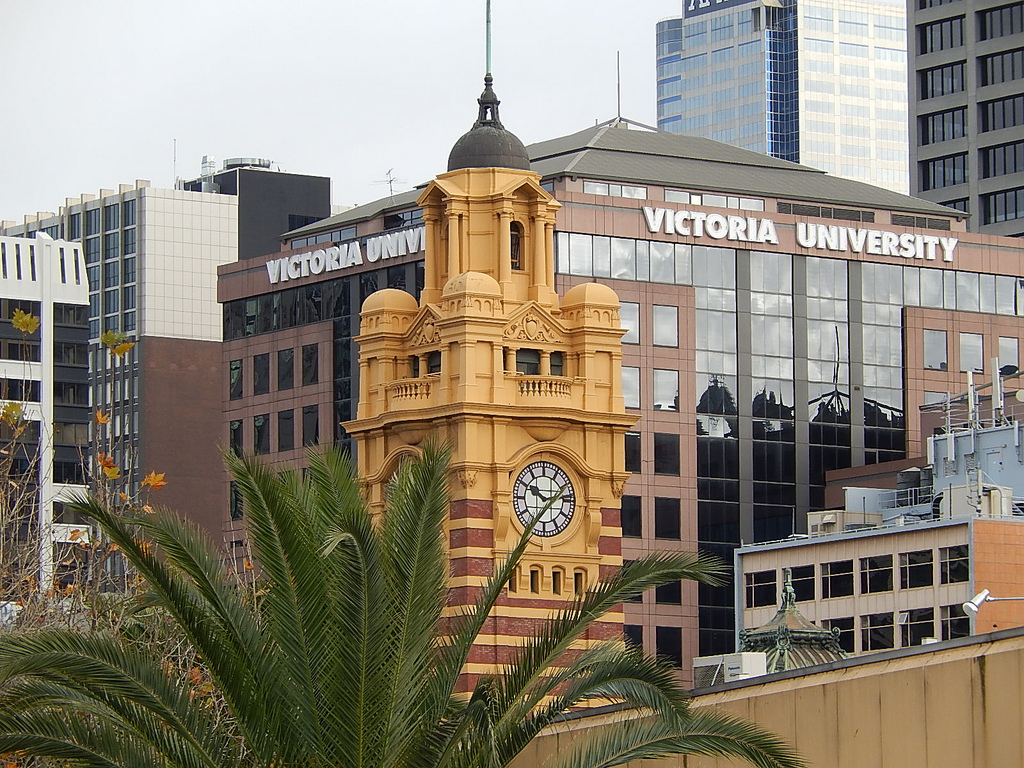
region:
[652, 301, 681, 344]
window on university building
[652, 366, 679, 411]
window on university building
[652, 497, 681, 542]
window on university building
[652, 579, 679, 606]
window on university building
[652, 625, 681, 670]
window on university building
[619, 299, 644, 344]
window on university building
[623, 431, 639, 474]
window on university building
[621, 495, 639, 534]
window on university building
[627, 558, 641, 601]
window on university building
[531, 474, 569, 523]
Clock has black hands.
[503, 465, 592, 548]
Numbers on clock are black.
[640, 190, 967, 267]
White letters on side of building.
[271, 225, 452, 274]
White letters on side of building.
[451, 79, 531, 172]
Top of building is black.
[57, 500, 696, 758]
Large green leaves on palm tree.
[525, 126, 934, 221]
Black roof on top of building.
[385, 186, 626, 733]
Clock on side of building.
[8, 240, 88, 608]
White and black colored building.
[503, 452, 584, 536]
clock on the side of building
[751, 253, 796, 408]
glass windows on the building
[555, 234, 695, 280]
glass windows on the building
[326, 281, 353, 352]
glass windows on the building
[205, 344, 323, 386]
glass windows on the building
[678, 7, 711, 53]
glass windows on the building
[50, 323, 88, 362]
glass windows on the building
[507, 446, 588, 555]
a clock on a tower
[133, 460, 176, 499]
a brown leaf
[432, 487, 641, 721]
red bricks on a yellow tower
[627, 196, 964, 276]
white sign on a building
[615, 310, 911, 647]
reflexion in the window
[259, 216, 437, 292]
white letters on a building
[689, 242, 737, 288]
building has a window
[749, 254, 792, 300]
building has a window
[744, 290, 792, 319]
building has a window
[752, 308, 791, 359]
building has a window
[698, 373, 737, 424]
building has a window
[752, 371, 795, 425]
building has a window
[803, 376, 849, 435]
building has a window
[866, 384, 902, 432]
building has a window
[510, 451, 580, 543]
large clock on tower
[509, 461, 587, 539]
large clock is round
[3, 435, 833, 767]
palm tree in front of building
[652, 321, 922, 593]
reflection in office windows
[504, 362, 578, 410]
balcony on top of tower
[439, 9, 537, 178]
steeple atop building tower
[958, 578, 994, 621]
light over small building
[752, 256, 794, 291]
a window on the building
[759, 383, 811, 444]
a window on the building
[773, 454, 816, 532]
a window on the building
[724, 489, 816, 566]
a window on the building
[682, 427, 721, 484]
a window on the building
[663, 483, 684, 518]
a window on the building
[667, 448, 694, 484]
a window on the building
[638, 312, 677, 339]
a window on the building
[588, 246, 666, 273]
a window on the building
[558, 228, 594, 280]
a window on a building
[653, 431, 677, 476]
a window on a building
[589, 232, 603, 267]
a window on a building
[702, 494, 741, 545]
a window on a building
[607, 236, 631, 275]
a window on a building